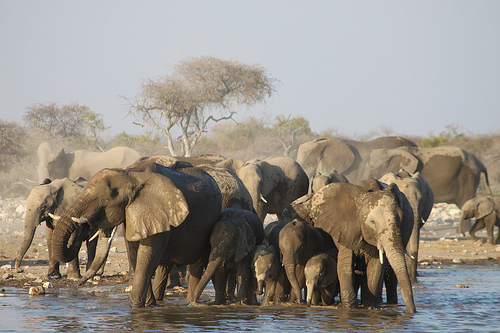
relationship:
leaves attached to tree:
[157, 95, 180, 106] [143, 113, 232, 155]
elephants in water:
[62, 162, 446, 309] [105, 303, 291, 322]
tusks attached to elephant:
[45, 210, 103, 229] [61, 186, 199, 304]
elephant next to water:
[61, 186, 199, 304] [105, 303, 291, 322]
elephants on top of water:
[62, 162, 446, 309] [105, 303, 291, 322]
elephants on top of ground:
[62, 162, 446, 309] [433, 247, 488, 268]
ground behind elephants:
[433, 247, 488, 268] [62, 162, 446, 309]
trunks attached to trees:
[161, 150, 196, 160] [17, 67, 350, 151]